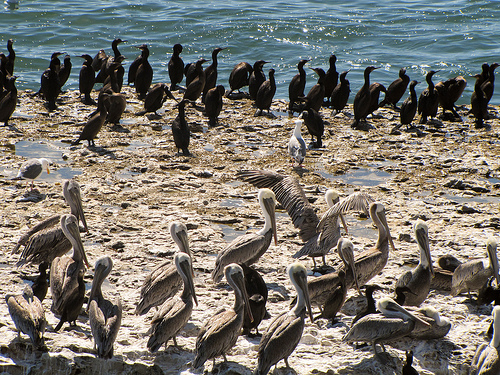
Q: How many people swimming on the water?
A: Zero.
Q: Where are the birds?
A: On the water.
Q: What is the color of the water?
A: Blue.